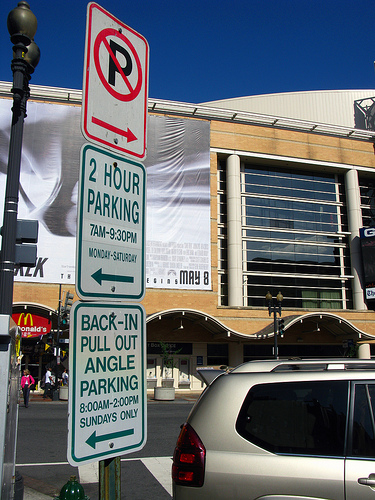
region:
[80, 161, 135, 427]
Parking boards are green and white.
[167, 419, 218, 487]
rear light is red.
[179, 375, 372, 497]
grey color car.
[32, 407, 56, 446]
road is grey.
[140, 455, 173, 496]
white lines on the road.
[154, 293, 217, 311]
wall is brown in color.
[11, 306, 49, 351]
Board is red and yellow.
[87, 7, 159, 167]
No parking board is in red and white.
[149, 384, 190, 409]
dustbin on sidewalk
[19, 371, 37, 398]
lady is crossing the road.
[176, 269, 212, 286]
The date on the white and black banner hanging on the building wall.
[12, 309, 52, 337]
McDonald's business sign on the building.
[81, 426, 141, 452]
The green arrow on the green and white sign that starts with B.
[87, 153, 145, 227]
2 Hour Parking on green and white sign.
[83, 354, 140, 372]
The word Angle on the green and white sign.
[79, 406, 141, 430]
The words Sunday Only.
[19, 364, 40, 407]
Lady in pink sweater.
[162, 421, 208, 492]
Red tail light of SUV.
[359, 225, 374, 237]
The letter G on sign near windows on the building.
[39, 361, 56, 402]
Man wearing a white t-shirt in front of McDonald's.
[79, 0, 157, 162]
NO PARKING SIGN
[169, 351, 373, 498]
GRAY SUV WITH TINTED WINDOWS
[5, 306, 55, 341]
MCDONALD'S SIGN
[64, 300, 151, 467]
GREEN AND WHITE PARKING SIGN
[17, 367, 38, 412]
WOMAN IN A PINK SWEATER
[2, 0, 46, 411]
LARGE STREET LAMP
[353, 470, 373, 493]
CAR DOOR HANDLE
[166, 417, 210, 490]
RED BRAKE LIGHT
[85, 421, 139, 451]
A GREEN ARROW POINTING LEFT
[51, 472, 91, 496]
THE TOP OF A FIRE HYDRANT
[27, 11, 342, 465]
a street in front of a large building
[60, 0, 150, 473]
three signs with parking directions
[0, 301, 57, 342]
sign for fast food restaurant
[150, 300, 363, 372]
undulating white line on structure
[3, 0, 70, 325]
lamppost in front of a large banner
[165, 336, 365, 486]
back end of a metallic-colored car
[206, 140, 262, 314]
tall and cylindrical support in front of large window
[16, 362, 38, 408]
standing woman looking down the street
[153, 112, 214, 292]
large wrinkled banner with month and day in corner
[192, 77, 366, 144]
curved roof behind large building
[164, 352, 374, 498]
The gray minivan is making a turn.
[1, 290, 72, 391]
McDonald's is across the street.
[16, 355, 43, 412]
A woman is crossing the street.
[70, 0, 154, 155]
No parking sign on a post.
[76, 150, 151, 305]
A two hour parking only sign.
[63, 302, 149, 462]
So many directions to follow.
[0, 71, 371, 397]
The buildings are all very tall.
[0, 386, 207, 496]
The street is clean and dry.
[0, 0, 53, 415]
The street lights are very quaint.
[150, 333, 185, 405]
The tree is spindly but green.